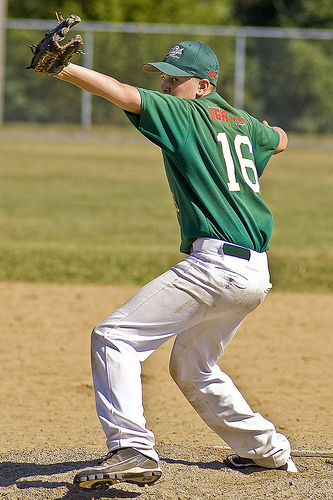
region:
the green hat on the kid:
[140, 41, 219, 86]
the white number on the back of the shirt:
[212, 130, 258, 198]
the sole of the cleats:
[77, 470, 163, 489]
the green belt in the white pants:
[223, 242, 251, 261]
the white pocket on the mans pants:
[207, 264, 250, 296]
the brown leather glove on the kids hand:
[24, 6, 84, 74]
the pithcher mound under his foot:
[281, 454, 298, 473]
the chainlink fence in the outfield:
[286, 25, 332, 144]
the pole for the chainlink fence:
[231, 29, 247, 106]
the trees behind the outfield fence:
[94, 0, 331, 26]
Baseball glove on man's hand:
[31, 14, 78, 71]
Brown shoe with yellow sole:
[71, 443, 165, 491]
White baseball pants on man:
[88, 241, 293, 462]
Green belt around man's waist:
[215, 242, 254, 261]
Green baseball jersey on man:
[134, 82, 275, 251]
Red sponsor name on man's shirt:
[205, 108, 248, 123]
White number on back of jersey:
[213, 131, 260, 189]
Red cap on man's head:
[137, 39, 220, 86]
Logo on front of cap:
[166, 43, 186, 62]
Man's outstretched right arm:
[249, 117, 288, 154]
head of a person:
[150, 29, 227, 108]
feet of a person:
[87, 442, 171, 484]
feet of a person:
[209, 436, 297, 474]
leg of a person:
[83, 346, 165, 443]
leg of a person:
[173, 346, 272, 441]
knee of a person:
[67, 321, 129, 355]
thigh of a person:
[104, 261, 230, 346]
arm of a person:
[95, 57, 159, 122]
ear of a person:
[192, 62, 221, 101]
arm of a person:
[246, 123, 304, 161]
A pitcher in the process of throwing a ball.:
[25, 11, 297, 491]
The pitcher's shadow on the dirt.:
[0, 456, 264, 498]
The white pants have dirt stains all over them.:
[90, 238, 290, 467]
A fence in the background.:
[0, 20, 332, 147]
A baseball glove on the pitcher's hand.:
[25, 13, 82, 76]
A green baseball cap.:
[142, 41, 218, 87]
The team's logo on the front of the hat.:
[165, 43, 184, 60]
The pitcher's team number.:
[216, 131, 261, 194]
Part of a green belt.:
[223, 242, 250, 260]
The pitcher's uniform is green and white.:
[25, 12, 297, 490]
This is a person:
[10, 5, 319, 494]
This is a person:
[25, 14, 314, 493]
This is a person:
[34, 9, 317, 498]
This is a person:
[18, 12, 309, 497]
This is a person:
[27, 11, 312, 489]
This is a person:
[28, 11, 313, 498]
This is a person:
[38, 13, 314, 497]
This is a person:
[29, 17, 285, 491]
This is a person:
[33, 19, 325, 494]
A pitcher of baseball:
[54, 41, 295, 487]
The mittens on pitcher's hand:
[28, 14, 84, 74]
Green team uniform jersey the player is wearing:
[123, 88, 278, 252]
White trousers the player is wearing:
[90, 238, 289, 466]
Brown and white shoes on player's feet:
[73, 449, 296, 491]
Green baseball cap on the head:
[139, 41, 218, 86]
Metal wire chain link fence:
[0, 20, 332, 130]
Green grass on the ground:
[0, 125, 332, 290]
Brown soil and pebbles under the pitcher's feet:
[0, 446, 331, 499]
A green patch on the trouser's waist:
[223, 243, 249, 259]